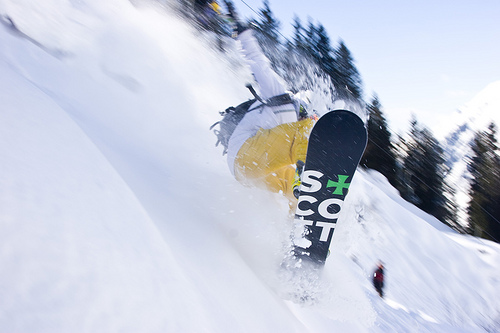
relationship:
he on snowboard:
[224, 22, 322, 221] [271, 106, 359, 296]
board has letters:
[295, 107, 367, 266] [294, 170, 324, 193]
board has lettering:
[295, 107, 367, 266] [317, 195, 342, 239]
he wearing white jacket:
[224, 22, 322, 221] [225, 28, 308, 178]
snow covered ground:
[0, 189, 494, 331] [2, 17, 196, 317]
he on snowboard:
[224, 22, 322, 221] [287, 103, 369, 283]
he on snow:
[224, 22, 322, 221] [0, 0, 499, 332]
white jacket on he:
[230, 29, 299, 184] [224, 22, 322, 221]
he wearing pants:
[224, 22, 322, 221] [253, 122, 317, 184]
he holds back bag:
[224, 22, 322, 221] [213, 93, 248, 146]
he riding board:
[224, 22, 322, 221] [275, 107, 367, 305]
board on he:
[275, 107, 367, 305] [224, 22, 322, 221]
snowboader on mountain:
[222, 34, 372, 302] [22, 10, 224, 290]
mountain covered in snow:
[0, 0, 498, 332] [0, 2, 222, 324]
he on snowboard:
[224, 22, 322, 221] [297, 97, 361, 258]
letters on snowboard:
[294, 160, 326, 195] [281, 91, 371, 282]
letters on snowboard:
[293, 192, 322, 219] [281, 91, 371, 282]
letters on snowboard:
[287, 216, 314, 251] [281, 91, 371, 282]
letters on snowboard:
[320, 197, 345, 219] [281, 91, 371, 282]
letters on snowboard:
[315, 219, 337, 242] [281, 91, 371, 282]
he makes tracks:
[224, 22, 322, 221] [230, 249, 293, 326]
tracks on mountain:
[230, 249, 293, 326] [0, 0, 499, 332]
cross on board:
[327, 172, 354, 196] [277, 126, 426, 299]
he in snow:
[203, 1, 337, 220] [0, 0, 499, 332]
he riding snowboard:
[224, 22, 322, 221] [261, 100, 372, 318]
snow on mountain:
[0, 0, 499, 332] [0, 0, 498, 332]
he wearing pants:
[224, 22, 322, 221] [233, 115, 317, 220]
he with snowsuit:
[224, 22, 322, 221] [210, 29, 312, 197]